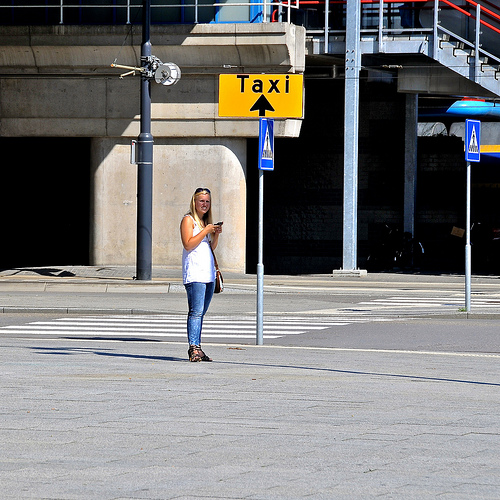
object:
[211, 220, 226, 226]
phone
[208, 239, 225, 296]
handbag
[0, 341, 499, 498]
concrete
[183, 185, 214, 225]
hair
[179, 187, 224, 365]
blonde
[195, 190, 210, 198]
glasses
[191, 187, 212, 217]
head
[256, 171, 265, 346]
pole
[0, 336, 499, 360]
lines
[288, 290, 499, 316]
street marking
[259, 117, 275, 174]
sign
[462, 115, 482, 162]
sign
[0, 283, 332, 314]
sidewalk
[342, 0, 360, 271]
gray pole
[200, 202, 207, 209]
nose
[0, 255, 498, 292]
sidewalk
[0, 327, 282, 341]
lines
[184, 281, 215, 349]
jean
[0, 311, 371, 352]
marking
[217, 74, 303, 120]
sign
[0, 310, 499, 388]
street